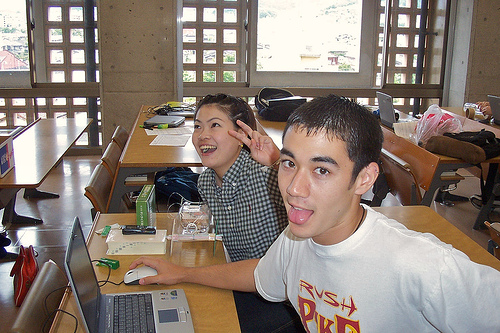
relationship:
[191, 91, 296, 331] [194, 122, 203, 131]
girl has eye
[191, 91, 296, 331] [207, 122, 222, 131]
girl has eye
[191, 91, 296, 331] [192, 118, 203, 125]
girl has eyebrow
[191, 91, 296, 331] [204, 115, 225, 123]
girl has eyebrow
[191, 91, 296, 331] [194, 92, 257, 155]
girl has hair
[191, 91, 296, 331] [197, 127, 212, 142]
girl has nose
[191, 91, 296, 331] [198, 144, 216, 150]
girl has teeth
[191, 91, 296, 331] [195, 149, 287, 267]
girl wears shirt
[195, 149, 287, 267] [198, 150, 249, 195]
shirt has collar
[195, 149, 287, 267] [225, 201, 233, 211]
shirt has button